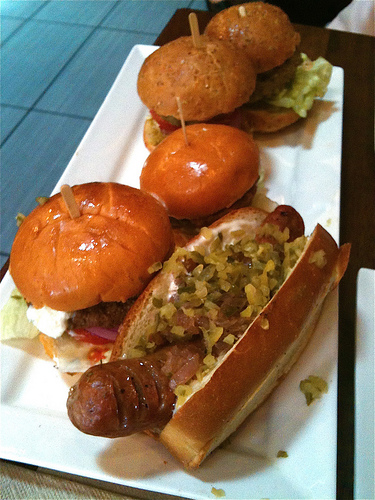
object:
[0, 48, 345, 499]
platter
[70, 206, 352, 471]
hotdog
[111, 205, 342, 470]
bread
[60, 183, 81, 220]
stick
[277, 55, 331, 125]
lettuce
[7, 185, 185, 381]
bread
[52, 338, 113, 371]
cheese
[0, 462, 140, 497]
mat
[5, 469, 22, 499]
lines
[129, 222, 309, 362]
relish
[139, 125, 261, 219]
bun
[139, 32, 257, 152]
crust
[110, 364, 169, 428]
splits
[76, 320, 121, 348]
onion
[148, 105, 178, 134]
tomato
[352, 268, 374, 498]
plate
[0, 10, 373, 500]
table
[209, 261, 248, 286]
pickles